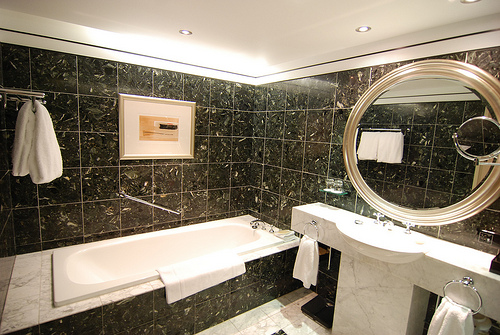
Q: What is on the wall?
A: A round mirror.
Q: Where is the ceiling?
A: In the bathroom.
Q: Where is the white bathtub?
A: In the corner, to the left of the sink.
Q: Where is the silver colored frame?
A: Above the bathtub, hanging on the far wall to the left.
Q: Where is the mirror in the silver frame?
A: Hanging above the sink.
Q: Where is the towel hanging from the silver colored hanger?
A: Above the back of the tub.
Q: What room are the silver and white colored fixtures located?
A: The bathroom.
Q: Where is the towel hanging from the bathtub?
A: On the one side where you enter.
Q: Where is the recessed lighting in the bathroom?
A: On the ceiling.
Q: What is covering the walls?
A: Large dark tiles.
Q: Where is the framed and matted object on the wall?
A: Above the tub and handrail.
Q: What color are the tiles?
A: Black.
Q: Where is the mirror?
A: On top of sink.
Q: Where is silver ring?
A: Sink.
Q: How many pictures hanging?
A: 1.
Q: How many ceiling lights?
A: 2.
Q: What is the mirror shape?
A: Round.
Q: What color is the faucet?
A: Silver.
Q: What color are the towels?
A: White.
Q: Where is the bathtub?
A: Left of sink.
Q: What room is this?
A: Bathroom.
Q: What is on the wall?
A: A painting.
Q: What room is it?
A: Bathroom.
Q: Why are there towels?
A: Dry off.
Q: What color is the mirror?
A: Gold.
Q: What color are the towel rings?
A: Silver.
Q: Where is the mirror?
A: Above the sink.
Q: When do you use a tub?
A: Take a bath.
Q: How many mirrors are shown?
A: Two.